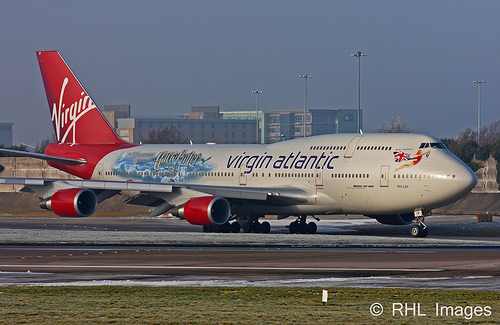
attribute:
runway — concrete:
[44, 203, 328, 276]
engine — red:
[61, 175, 103, 224]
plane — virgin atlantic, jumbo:
[37, 58, 477, 241]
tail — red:
[32, 36, 126, 153]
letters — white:
[54, 79, 105, 147]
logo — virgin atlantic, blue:
[224, 147, 351, 184]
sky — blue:
[27, 5, 484, 106]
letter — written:
[52, 83, 66, 146]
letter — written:
[59, 100, 74, 140]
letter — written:
[67, 98, 81, 141]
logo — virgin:
[49, 79, 125, 135]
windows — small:
[299, 141, 399, 163]